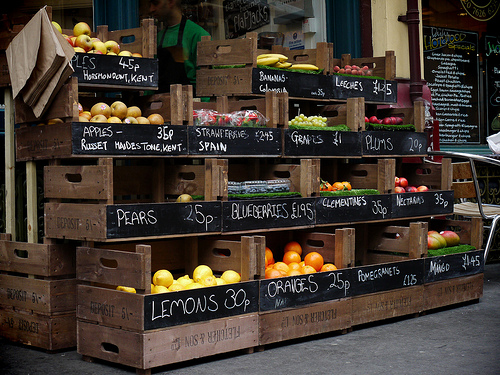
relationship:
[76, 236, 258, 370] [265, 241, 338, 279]
bin of fruit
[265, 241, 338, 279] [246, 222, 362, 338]
fruit in bin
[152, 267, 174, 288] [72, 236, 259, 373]
lemon in bin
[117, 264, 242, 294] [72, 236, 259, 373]
fruits in bin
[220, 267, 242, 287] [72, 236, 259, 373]
lemon in bin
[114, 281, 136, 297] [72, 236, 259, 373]
lemon in bin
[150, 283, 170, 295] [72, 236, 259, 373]
lemon in bin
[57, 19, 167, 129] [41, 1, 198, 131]
apples in bins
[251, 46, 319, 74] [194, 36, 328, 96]
bananas in bin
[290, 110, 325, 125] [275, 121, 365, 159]
grapes in bin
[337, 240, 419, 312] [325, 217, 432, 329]
fruits in box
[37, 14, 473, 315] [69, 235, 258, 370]
fruits in box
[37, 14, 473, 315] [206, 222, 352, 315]
fruits in bin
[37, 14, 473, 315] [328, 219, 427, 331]
fruits in box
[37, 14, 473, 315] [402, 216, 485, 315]
fruits in box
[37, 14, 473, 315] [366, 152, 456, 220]
fruits in box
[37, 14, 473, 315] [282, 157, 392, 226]
fruits in box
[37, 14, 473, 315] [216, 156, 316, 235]
fruits in box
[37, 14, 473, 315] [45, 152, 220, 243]
fruits in box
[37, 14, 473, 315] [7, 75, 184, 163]
fruits in box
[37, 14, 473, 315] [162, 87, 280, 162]
fruits in box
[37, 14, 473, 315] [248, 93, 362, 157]
fruits in box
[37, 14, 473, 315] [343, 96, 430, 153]
fruits in box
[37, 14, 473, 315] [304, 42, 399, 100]
fruits in box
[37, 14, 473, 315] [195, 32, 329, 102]
fruits in bin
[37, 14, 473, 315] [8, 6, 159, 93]
fruits in bins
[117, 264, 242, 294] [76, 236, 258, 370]
fruits in bin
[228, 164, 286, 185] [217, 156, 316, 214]
fruits on box